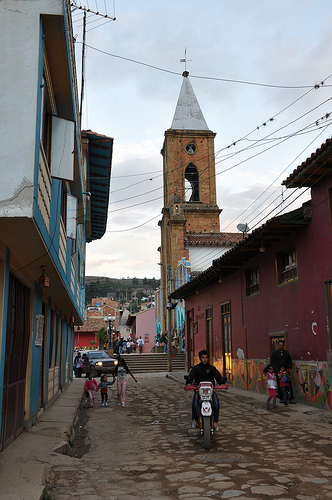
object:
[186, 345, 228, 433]
man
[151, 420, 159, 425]
stones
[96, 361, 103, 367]
headlights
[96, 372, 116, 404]
kids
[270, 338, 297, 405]
man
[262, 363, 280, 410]
children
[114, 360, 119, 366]
light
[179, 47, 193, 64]
weather vane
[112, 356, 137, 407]
woman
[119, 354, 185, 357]
steps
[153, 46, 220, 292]
church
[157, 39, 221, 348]
bell tower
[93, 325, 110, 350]
trees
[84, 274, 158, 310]
hill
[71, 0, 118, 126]
antenna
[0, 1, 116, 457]
building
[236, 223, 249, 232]
disk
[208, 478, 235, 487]
stone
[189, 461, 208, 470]
stone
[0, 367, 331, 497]
ground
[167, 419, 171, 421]
stone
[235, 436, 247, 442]
stone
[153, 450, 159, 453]
stone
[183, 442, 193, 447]
stone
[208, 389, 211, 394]
headlights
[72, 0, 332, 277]
sky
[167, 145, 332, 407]
side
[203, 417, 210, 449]
tire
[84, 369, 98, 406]
girls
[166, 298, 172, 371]
pole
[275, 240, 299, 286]
windows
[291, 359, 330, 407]
mural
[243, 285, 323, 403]
wall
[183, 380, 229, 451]
motorbike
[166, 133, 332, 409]
building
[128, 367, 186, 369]
stairway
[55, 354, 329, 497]
street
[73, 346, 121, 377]
car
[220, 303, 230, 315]
window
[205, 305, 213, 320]
window